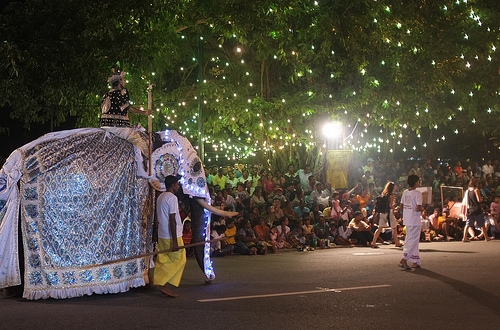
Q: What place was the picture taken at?
A: It was taken at the road.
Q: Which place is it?
A: It is a road.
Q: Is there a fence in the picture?
A: No, there are no fences.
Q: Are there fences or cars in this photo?
A: No, there are no fences or cars.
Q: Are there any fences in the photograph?
A: No, there are no fences.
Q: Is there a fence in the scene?
A: No, there are no fences.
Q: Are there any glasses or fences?
A: No, there are no fences or glasses.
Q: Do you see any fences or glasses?
A: No, there are no fences or glasses.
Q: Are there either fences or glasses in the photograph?
A: No, there are no fences or glasses.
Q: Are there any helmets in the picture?
A: No, there are no helmets.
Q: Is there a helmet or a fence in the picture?
A: No, there are no helmets or fences.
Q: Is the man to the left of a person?
A: Yes, the man is to the left of a person.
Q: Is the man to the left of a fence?
A: No, the man is to the left of a person.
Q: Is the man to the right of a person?
A: No, the man is to the left of a person.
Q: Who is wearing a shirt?
A: The man is wearing a shirt.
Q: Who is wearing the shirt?
A: The man is wearing a shirt.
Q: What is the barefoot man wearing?
A: The man is wearing a shirt.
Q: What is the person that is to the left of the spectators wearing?
A: The man is wearing a shirt.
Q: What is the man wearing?
A: The man is wearing a shirt.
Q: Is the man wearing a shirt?
A: Yes, the man is wearing a shirt.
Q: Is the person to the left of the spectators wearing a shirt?
A: Yes, the man is wearing a shirt.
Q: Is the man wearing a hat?
A: No, the man is wearing a shirt.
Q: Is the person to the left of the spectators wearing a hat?
A: No, the man is wearing a shirt.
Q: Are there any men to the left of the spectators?
A: Yes, there is a man to the left of the spectators.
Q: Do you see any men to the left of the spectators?
A: Yes, there is a man to the left of the spectators.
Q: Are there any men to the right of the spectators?
A: No, the man is to the left of the spectators.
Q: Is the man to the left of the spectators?
A: Yes, the man is to the left of the spectators.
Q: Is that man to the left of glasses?
A: No, the man is to the left of the spectators.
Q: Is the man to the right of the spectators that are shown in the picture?
A: No, the man is to the left of the spectators.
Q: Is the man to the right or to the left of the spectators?
A: The man is to the left of the spectators.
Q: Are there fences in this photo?
A: No, there are no fences.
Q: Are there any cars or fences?
A: No, there are no fences or cars.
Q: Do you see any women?
A: Yes, there is a woman.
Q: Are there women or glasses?
A: Yes, there is a woman.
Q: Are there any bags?
A: No, there are no bags.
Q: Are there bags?
A: No, there are no bags.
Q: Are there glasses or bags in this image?
A: No, there are no bags or glasses.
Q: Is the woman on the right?
A: Yes, the woman is on the right of the image.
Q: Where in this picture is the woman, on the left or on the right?
A: The woman is on the right of the image.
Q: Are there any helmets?
A: No, there are no helmets.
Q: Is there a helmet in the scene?
A: No, there are no helmets.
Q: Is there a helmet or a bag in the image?
A: No, there are no helmets or bags.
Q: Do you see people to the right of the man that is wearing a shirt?
A: Yes, there is a person to the right of the man.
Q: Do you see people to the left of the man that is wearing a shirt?
A: No, the person is to the right of the man.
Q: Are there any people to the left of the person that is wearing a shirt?
A: No, the person is to the right of the man.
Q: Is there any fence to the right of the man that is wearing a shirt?
A: No, there is a person to the right of the man.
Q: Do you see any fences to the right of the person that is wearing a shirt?
A: No, there is a person to the right of the man.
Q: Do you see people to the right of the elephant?
A: Yes, there is a person to the right of the elephant.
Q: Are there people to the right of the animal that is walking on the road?
A: Yes, there is a person to the right of the elephant.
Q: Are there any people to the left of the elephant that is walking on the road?
A: No, the person is to the right of the elephant.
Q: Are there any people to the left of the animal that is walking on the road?
A: No, the person is to the right of the elephant.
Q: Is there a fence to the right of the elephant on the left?
A: No, there is a person to the right of the elephant.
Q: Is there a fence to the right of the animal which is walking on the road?
A: No, there is a person to the right of the elephant.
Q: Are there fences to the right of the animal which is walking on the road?
A: No, there is a person to the right of the elephant.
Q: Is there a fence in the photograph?
A: No, there are no fences.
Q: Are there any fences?
A: No, there are no fences.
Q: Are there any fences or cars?
A: No, there are no fences or cars.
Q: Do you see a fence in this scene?
A: No, there are no fences.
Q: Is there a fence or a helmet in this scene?
A: No, there are no fences or helmets.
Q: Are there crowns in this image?
A: No, there are no crowns.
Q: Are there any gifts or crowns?
A: No, there are no crowns or gifts.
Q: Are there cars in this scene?
A: No, there are no cars.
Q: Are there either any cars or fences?
A: No, there are no cars or fences.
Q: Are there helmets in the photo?
A: No, there are no helmets.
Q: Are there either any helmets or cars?
A: No, there are no helmets or cars.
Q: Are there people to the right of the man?
A: Yes, there is a person to the right of the man.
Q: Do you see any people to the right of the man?
A: Yes, there is a person to the right of the man.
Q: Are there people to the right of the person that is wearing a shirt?
A: Yes, there is a person to the right of the man.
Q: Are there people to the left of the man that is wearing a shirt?
A: No, the person is to the right of the man.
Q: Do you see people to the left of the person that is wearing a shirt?
A: No, the person is to the right of the man.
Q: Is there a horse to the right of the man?
A: No, there is a person to the right of the man.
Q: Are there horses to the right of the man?
A: No, there is a person to the right of the man.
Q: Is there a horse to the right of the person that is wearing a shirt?
A: No, there is a person to the right of the man.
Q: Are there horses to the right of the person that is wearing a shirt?
A: No, there is a person to the right of the man.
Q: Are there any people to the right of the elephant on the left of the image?
A: Yes, there is a person to the right of the elephant.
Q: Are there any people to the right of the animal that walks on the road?
A: Yes, there is a person to the right of the elephant.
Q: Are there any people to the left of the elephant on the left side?
A: No, the person is to the right of the elephant.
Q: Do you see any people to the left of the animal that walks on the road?
A: No, the person is to the right of the elephant.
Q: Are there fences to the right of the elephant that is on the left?
A: No, there is a person to the right of the elephant.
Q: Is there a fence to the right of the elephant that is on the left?
A: No, there is a person to the right of the elephant.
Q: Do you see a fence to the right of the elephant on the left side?
A: No, there is a person to the right of the elephant.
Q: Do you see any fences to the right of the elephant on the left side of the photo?
A: No, there is a person to the right of the elephant.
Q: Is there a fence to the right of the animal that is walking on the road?
A: No, there is a person to the right of the elephant.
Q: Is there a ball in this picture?
A: No, there are no balls.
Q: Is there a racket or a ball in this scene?
A: No, there are no balls or rackets.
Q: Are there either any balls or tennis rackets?
A: No, there are no balls or tennis rackets.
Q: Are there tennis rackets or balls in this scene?
A: No, there are no balls or tennis rackets.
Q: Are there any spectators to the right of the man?
A: Yes, there are spectators to the right of the man.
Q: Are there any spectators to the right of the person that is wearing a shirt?
A: Yes, there are spectators to the right of the man.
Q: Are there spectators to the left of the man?
A: No, the spectators are to the right of the man.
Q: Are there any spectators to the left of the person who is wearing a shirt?
A: No, the spectators are to the right of the man.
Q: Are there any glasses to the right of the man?
A: No, there are spectators to the right of the man.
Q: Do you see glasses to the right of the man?
A: No, there are spectators to the right of the man.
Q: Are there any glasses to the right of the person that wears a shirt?
A: No, there are spectators to the right of the man.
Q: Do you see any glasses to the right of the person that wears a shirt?
A: No, there are spectators to the right of the man.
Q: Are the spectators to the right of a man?
A: Yes, the spectators are to the right of a man.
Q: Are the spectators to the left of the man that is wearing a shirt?
A: No, the spectators are to the right of the man.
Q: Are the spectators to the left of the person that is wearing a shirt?
A: No, the spectators are to the right of the man.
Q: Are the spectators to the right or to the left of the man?
A: The spectators are to the right of the man.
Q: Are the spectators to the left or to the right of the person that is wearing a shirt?
A: The spectators are to the right of the man.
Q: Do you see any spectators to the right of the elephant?
A: Yes, there are spectators to the right of the elephant.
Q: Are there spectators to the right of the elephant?
A: Yes, there are spectators to the right of the elephant.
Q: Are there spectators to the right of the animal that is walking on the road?
A: Yes, there are spectators to the right of the elephant.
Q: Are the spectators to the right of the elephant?
A: Yes, the spectators are to the right of the elephant.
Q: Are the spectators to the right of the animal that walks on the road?
A: Yes, the spectators are to the right of the elephant.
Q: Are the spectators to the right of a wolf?
A: No, the spectators are to the right of the elephant.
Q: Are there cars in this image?
A: No, there are no cars.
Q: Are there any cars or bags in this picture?
A: No, there are no cars or bags.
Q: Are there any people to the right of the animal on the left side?
A: Yes, there is a person to the right of the elephant.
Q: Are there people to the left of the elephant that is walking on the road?
A: No, the person is to the right of the elephant.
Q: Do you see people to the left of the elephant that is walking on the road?
A: No, the person is to the right of the elephant.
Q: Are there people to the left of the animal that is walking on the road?
A: No, the person is to the right of the elephant.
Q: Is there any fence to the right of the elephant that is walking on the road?
A: No, there is a person to the right of the elephant.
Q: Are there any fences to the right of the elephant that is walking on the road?
A: No, there is a person to the right of the elephant.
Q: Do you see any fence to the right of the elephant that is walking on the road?
A: No, there is a person to the right of the elephant.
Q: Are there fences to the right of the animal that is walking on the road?
A: No, there is a person to the right of the elephant.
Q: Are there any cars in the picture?
A: No, there are no cars.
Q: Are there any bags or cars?
A: No, there are no cars or bags.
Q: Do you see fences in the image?
A: No, there are no fences.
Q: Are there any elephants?
A: Yes, there is an elephant.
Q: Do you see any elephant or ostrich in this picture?
A: Yes, there is an elephant.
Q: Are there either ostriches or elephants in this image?
A: Yes, there is an elephant.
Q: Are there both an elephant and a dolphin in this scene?
A: No, there is an elephant but no dolphins.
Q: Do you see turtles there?
A: No, there are no turtles.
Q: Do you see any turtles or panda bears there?
A: No, there are no turtles or panda bears.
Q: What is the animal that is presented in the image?
A: The animal is an elephant.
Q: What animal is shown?
A: The animal is an elephant.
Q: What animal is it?
A: The animal is an elephant.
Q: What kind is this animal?
A: This is an elephant.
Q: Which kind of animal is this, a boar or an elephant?
A: This is an elephant.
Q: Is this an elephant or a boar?
A: This is an elephant.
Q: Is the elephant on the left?
A: Yes, the elephant is on the left of the image.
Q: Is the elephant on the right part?
A: No, the elephant is on the left of the image.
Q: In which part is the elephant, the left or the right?
A: The elephant is on the left of the image.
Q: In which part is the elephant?
A: The elephant is on the left of the image.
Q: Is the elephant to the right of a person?
A: No, the elephant is to the left of a person.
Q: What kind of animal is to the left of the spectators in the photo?
A: The animal is an elephant.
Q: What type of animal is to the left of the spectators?
A: The animal is an elephant.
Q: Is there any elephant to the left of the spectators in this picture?
A: Yes, there is an elephant to the left of the spectators.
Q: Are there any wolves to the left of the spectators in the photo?
A: No, there is an elephant to the left of the spectators.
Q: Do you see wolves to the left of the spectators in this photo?
A: No, there is an elephant to the left of the spectators.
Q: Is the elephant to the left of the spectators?
A: Yes, the elephant is to the left of the spectators.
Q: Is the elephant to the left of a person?
A: Yes, the elephant is to the left of a person.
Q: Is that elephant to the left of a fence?
A: No, the elephant is to the left of a person.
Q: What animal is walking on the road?
A: The elephant is walking on the road.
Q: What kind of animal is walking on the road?
A: The animal is an elephant.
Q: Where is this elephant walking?
A: The elephant is walking on the road.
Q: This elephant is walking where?
A: The elephant is walking on the road.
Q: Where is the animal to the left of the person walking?
A: The elephant is walking on the road.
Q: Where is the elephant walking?
A: The elephant is walking on the road.